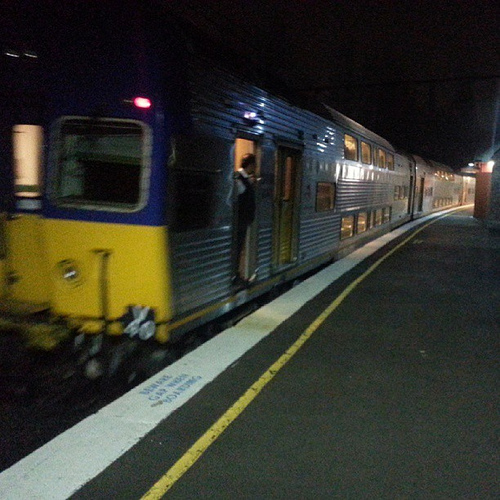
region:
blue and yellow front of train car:
[10, 77, 171, 349]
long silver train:
[122, 97, 482, 337]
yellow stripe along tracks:
[132, 219, 417, 498]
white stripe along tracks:
[1, 221, 396, 497]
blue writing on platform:
[135, 364, 205, 410]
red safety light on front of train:
[130, 94, 152, 114]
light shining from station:
[468, 122, 494, 234]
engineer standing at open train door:
[231, 125, 263, 296]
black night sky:
[287, 17, 471, 87]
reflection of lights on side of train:
[333, 158, 416, 188]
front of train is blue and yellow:
[3, 55, 202, 360]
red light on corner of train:
[125, 91, 160, 122]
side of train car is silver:
[155, 79, 400, 349]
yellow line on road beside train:
[127, 187, 483, 498]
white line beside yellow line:
[20, 176, 470, 491]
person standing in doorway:
[223, 118, 263, 293]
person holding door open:
[237, 108, 262, 290]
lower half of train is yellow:
[0, 211, 189, 353]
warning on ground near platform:
[124, 362, 204, 409]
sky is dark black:
[369, 2, 492, 149]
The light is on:
[96, 91, 199, 158]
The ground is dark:
[308, 278, 498, 438]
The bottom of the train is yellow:
[3, 207, 205, 371]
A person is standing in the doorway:
[215, 137, 310, 304]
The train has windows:
[313, 126, 459, 246]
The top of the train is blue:
[31, 29, 245, 234]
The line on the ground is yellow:
[101, 328, 429, 496]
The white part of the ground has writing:
[94, 367, 281, 449]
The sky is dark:
[285, 20, 456, 162]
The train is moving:
[101, 108, 498, 280]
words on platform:
[127, 365, 213, 408]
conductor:
[228, 147, 267, 294]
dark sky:
[183, 7, 498, 71]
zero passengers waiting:
[175, 200, 493, 495]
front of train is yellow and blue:
[5, 76, 169, 342]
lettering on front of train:
[118, 302, 161, 344]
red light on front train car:
[120, 87, 160, 118]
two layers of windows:
[331, 122, 399, 237]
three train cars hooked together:
[10, 88, 491, 341]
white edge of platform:
[20, 355, 243, 489]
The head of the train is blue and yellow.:
[0, 50, 180, 350]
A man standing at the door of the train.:
[222, 142, 262, 287]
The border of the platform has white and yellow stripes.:
[7, 405, 285, 496]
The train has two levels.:
[340, 126, 390, 236]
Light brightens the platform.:
[447, 155, 492, 225]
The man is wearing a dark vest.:
[230, 165, 250, 225]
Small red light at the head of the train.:
[127, 95, 152, 105]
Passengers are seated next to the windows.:
[340, 130, 400, 170]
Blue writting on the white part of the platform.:
[127, 365, 202, 407]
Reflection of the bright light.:
[335, 162, 395, 182]